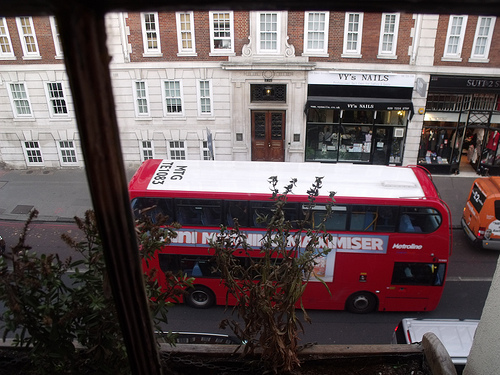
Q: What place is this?
A: It is a road.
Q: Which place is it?
A: It is a road.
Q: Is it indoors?
A: Yes, it is indoors.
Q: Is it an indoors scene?
A: Yes, it is indoors.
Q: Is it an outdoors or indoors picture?
A: It is indoors.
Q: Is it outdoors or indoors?
A: It is indoors.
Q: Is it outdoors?
A: No, it is indoors.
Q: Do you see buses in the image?
A: Yes, there is a bus.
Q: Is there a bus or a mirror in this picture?
A: Yes, there is a bus.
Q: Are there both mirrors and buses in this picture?
A: No, there is a bus but no mirrors.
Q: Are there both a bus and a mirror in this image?
A: No, there is a bus but no mirrors.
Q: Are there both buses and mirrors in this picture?
A: No, there is a bus but no mirrors.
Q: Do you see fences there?
A: No, there are no fences.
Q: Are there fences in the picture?
A: No, there are no fences.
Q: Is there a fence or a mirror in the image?
A: No, there are no fences or mirrors.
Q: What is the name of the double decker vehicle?
A: The vehicle is a bus.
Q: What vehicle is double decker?
A: The vehicle is a bus.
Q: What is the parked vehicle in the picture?
A: The vehicle is a bus.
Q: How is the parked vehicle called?
A: The vehicle is a bus.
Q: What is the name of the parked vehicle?
A: The vehicle is a bus.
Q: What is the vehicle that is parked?
A: The vehicle is a bus.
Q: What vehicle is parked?
A: The vehicle is a bus.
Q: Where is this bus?
A: The bus is on the road.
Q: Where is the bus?
A: The bus is on the road.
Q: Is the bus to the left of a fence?
A: No, the bus is to the left of the vehicle.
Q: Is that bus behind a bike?
A: No, the bus is behind the vehicle.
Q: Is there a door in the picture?
A: Yes, there is a door.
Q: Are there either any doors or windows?
A: Yes, there is a door.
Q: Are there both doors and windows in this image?
A: Yes, there are both a door and windows.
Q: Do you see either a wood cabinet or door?
A: Yes, there is a wood door.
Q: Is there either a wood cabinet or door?
A: Yes, there is a wood door.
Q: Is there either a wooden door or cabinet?
A: Yes, there is a wood door.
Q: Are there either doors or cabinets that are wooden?
A: Yes, the door is wooden.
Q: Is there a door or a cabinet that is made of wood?
A: Yes, the door is made of wood.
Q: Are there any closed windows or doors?
A: Yes, there is a closed door.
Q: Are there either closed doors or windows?
A: Yes, there is a closed door.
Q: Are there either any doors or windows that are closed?
A: Yes, the door is closed.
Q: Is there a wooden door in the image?
A: Yes, there is a wood door.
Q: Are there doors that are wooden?
A: Yes, there is a door that is wooden.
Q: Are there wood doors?
A: Yes, there is a door that is made of wood.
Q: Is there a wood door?
A: Yes, there is a door that is made of wood.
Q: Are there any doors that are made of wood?
A: Yes, there is a door that is made of wood.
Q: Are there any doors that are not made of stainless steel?
A: Yes, there is a door that is made of wood.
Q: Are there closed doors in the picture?
A: Yes, there is a closed door.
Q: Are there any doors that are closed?
A: Yes, there is a door that is closed.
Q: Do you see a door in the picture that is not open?
A: Yes, there is an closed door.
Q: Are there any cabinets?
A: No, there are no cabinets.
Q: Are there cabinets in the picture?
A: No, there are no cabinets.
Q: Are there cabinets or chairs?
A: No, there are no cabinets or chairs.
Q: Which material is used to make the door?
A: The door is made of wood.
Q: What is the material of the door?
A: The door is made of wood.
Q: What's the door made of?
A: The door is made of wood.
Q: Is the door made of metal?
A: No, the door is made of wood.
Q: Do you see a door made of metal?
A: No, there is a door but it is made of wood.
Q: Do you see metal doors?
A: No, there is a door but it is made of wood.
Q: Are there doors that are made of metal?
A: No, there is a door but it is made of wood.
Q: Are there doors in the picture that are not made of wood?
A: No, there is a door but it is made of wood.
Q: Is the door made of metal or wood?
A: The door is made of wood.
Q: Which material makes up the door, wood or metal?
A: The door is made of wood.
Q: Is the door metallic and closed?
A: No, the door is closed but wooden.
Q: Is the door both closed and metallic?
A: No, the door is closed but wooden.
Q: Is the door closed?
A: Yes, the door is closed.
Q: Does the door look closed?
A: Yes, the door is closed.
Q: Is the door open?
A: No, the door is closed.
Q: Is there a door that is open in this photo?
A: No, there is a door but it is closed.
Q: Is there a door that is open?
A: No, there is a door but it is closed.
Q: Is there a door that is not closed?
A: No, there is a door but it is closed.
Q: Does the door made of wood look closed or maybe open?
A: The door is closed.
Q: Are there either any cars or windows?
A: Yes, there are windows.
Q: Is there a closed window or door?
A: Yes, there are closed windows.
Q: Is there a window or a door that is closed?
A: Yes, the windows are closed.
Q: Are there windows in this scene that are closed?
A: Yes, there are closed windows.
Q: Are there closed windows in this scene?
A: Yes, there are closed windows.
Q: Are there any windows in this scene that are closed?
A: Yes, there are windows that are closed.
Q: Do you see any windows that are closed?
A: Yes, there are windows that are closed.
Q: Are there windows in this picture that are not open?
A: Yes, there are closed windows.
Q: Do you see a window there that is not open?
A: Yes, there are closed windows.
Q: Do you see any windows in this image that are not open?
A: Yes, there are closed windows.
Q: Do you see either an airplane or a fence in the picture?
A: No, there are no fences or airplanes.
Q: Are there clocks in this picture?
A: No, there are no clocks.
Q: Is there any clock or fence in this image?
A: No, there are no clocks or fences.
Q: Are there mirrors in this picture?
A: No, there are no mirrors.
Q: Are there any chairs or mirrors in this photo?
A: No, there are no mirrors or chairs.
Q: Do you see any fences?
A: No, there are no fences.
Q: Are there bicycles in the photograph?
A: No, there are no bicycles.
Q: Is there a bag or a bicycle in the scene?
A: No, there are no bicycles or bags.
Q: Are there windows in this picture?
A: Yes, there is a window.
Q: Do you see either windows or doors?
A: Yes, there is a window.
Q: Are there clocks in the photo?
A: No, there are no clocks.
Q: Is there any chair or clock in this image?
A: No, there are no clocks or chairs.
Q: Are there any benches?
A: No, there are no benches.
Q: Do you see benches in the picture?
A: No, there are no benches.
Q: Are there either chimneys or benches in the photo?
A: No, there are no benches or chimneys.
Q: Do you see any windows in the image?
A: Yes, there is a window.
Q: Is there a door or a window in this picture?
A: Yes, there is a window.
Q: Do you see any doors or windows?
A: Yes, there is a window.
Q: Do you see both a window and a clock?
A: No, there is a window but no clocks.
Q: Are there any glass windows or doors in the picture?
A: Yes, there is a glass window.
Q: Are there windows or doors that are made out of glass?
A: Yes, the window is made of glass.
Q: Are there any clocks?
A: No, there are no clocks.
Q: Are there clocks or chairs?
A: No, there are no clocks or chairs.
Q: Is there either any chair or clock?
A: No, there are no clocks or chairs.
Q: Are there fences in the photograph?
A: No, there are no fences.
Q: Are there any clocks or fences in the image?
A: No, there are no fences or clocks.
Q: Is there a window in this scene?
A: Yes, there is a window.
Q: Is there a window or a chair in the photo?
A: Yes, there is a window.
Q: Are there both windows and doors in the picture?
A: Yes, there are both a window and a door.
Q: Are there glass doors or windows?
A: Yes, there is a glass window.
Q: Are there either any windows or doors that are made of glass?
A: Yes, the window is made of glass.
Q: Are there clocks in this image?
A: No, there are no clocks.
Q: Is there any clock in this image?
A: No, there are no clocks.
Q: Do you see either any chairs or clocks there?
A: No, there are no clocks or chairs.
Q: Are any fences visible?
A: No, there are no fences.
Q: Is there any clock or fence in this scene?
A: No, there are no fences or clocks.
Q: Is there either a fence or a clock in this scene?
A: No, there are no fences or clocks.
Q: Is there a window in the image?
A: Yes, there is a window.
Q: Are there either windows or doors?
A: Yes, there is a window.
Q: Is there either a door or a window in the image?
A: Yes, there is a window.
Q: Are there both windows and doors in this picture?
A: Yes, there are both a window and doors.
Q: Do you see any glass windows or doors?
A: Yes, there is a glass window.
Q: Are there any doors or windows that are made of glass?
A: Yes, the window is made of glass.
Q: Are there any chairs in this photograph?
A: No, there are no chairs.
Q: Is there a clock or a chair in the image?
A: No, there are no chairs or clocks.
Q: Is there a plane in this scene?
A: No, there are no airplanes.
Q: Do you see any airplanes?
A: No, there are no airplanes.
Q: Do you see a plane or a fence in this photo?
A: No, there are no airplanes or fences.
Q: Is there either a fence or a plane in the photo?
A: No, there are no airplanes or fences.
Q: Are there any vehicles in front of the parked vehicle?
A: Yes, there is a vehicle in front of the bus.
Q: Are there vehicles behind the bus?
A: No, the vehicle is in front of the bus.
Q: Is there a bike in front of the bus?
A: No, there is a vehicle in front of the bus.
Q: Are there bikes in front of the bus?
A: No, there is a vehicle in front of the bus.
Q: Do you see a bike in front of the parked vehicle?
A: No, there is a vehicle in front of the bus.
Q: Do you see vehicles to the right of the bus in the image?
A: Yes, there is a vehicle to the right of the bus.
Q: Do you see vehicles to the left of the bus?
A: No, the vehicle is to the right of the bus.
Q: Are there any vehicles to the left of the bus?
A: No, the vehicle is to the right of the bus.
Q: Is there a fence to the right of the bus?
A: No, there is a vehicle to the right of the bus.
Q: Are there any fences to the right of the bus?
A: No, there is a vehicle to the right of the bus.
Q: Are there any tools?
A: No, there are no tools.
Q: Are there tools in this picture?
A: No, there are no tools.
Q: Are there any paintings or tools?
A: No, there are no tools or paintings.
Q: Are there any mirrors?
A: No, there are no mirrors.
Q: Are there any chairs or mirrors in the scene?
A: No, there are no mirrors or chairs.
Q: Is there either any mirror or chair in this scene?
A: No, there are no mirrors or chairs.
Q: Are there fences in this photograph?
A: No, there are no fences.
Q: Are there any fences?
A: No, there are no fences.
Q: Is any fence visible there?
A: No, there are no fences.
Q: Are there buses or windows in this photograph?
A: Yes, there is a window.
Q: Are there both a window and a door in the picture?
A: Yes, there are both a window and a door.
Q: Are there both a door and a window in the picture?
A: Yes, there are both a window and a door.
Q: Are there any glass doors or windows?
A: Yes, there is a glass window.